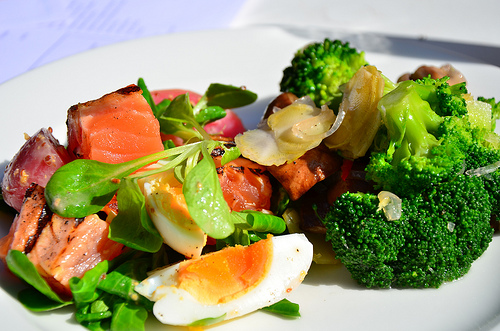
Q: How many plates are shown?
A: 1.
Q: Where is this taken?
A: Table.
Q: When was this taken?
A: Daytime.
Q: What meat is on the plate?
A: Salmon.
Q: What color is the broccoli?
A: Green.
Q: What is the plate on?
A: Tablecloth.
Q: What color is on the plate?
A: White.